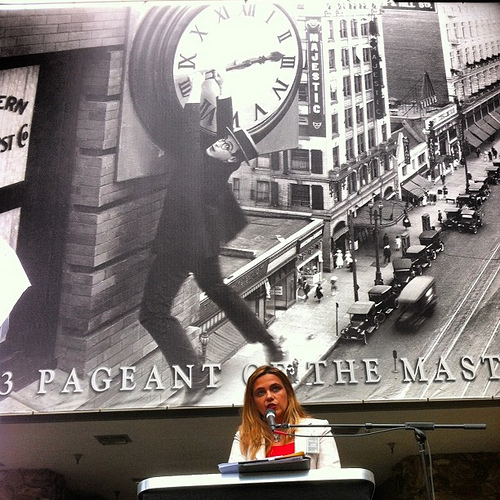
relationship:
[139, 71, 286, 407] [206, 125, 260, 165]
man has a head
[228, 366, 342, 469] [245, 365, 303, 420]
woman has a head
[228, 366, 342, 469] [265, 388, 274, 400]
woman has a nose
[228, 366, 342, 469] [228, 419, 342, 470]
woman wearing jacket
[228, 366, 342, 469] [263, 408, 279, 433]
woman talking into microphone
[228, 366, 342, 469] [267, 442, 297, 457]
woman wearing shirt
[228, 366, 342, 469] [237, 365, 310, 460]
woman has hair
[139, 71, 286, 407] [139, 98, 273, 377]
man wearing suit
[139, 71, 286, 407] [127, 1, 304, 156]
man hanging from clock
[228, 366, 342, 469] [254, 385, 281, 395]
woman has eyes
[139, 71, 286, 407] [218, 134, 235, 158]
man has on glasses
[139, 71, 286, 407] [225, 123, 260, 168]
man has on a hat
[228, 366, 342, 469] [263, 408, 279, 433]
woman speaking in microphone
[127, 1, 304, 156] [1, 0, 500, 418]
clock on photo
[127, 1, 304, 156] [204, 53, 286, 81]
clock has hands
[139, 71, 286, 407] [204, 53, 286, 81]
man hanging from hands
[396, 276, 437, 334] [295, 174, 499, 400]
car on street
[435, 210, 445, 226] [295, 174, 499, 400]
person walking on street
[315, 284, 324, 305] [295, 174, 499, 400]
person walking on street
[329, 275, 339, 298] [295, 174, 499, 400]
person walking on street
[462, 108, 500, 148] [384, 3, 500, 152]
awning on building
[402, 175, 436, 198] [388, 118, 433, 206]
awning on building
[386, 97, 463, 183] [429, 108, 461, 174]
building has store front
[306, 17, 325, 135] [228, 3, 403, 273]
sign on side of building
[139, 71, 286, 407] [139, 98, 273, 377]
man in suit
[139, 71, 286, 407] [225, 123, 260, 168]
man in hat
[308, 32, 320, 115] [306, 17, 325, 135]
majestic on sign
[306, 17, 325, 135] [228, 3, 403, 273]
sign on building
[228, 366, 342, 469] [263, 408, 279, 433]
woman speaking into microphone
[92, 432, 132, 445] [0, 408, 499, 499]
vent on ceiling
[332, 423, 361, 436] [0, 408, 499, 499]
vent on ceiling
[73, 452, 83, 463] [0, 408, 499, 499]
fire sprinkler on ceiling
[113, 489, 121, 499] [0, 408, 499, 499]
fire sprinkler on ceiling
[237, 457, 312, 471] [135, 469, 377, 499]
folder on podium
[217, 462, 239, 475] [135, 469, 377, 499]
papers are on podium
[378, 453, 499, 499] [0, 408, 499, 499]
pillar holding up ceiling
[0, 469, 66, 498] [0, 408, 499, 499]
pillar holding up ceiling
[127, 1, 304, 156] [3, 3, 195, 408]
clock on building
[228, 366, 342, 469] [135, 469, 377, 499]
woman standing at podium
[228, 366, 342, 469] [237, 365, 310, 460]
woman with hair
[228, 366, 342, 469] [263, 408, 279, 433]
woman talking in microphone